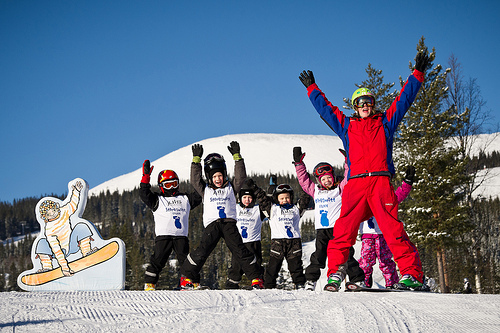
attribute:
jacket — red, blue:
[302, 66, 427, 180]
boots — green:
[322, 265, 427, 295]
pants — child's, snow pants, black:
[176, 215, 263, 287]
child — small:
[125, 154, 206, 299]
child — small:
[262, 170, 311, 288]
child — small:
[178, 139, 266, 290]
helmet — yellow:
[352, 86, 377, 108]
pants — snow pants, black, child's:
[145, 232, 194, 279]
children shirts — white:
[142, 45, 317, 299]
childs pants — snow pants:
[289, 226, 389, 289]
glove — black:
[226, 138, 241, 157]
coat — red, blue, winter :
[305, 67, 426, 178]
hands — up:
[414, 48, 431, 72]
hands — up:
[293, 148, 303, 160]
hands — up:
[227, 141, 239, 154]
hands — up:
[269, 175, 276, 182]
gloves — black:
[402, 34, 455, 96]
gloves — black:
[287, 62, 319, 87]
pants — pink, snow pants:
[293, 145, 448, 300]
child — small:
[357, 165, 417, 289]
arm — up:
[394, 165, 417, 204]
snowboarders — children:
[104, 29, 474, 328]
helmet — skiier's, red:
[158, 169, 179, 194]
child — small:
[189, 133, 251, 288]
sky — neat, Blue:
[24, 10, 494, 177]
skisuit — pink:
[304, 72, 426, 279]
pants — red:
[323, 173, 425, 280]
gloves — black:
[293, 45, 433, 85]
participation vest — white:
[88, 173, 375, 243]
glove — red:
[125, 146, 161, 193]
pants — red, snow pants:
[289, 156, 432, 296]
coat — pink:
[292, 150, 353, 246]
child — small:
[148, 180, 194, 266]